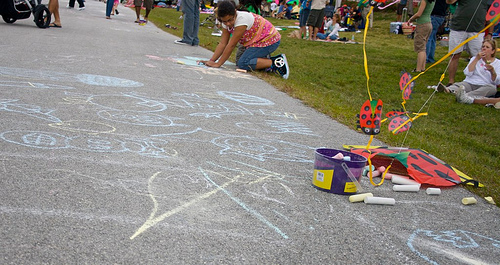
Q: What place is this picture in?
A: It is at the pavement.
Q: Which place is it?
A: It is a pavement.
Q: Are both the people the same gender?
A: Yes, all the people are female.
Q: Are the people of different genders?
A: No, all the people are female.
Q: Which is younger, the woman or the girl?
A: The girl is younger than the woman.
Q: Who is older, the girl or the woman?
A: The woman is older than the girl.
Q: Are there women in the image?
A: Yes, there is a woman.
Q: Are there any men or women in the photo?
A: Yes, there is a woman.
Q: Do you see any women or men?
A: Yes, there is a woman.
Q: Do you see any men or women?
A: Yes, there is a woman.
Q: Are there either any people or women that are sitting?
A: Yes, the woman is sitting.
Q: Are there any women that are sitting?
A: Yes, there is a woman that is sitting.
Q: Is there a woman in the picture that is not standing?
A: Yes, there is a woman that is sitting.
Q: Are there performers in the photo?
A: No, there are no performers.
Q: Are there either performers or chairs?
A: No, there are no performers or chairs.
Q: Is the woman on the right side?
A: Yes, the woman is on the right of the image.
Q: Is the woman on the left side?
A: No, the woman is on the right of the image.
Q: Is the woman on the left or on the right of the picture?
A: The woman is on the right of the image.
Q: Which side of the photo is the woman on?
A: The woman is on the right of the image.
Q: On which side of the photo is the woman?
A: The woman is on the right of the image.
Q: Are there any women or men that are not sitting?
A: No, there is a woman but she is sitting.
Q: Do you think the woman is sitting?
A: Yes, the woman is sitting.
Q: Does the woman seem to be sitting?
A: Yes, the woman is sitting.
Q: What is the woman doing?
A: The woman is sitting.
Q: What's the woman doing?
A: The woman is sitting.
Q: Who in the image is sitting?
A: The woman is sitting.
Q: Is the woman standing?
A: No, the woman is sitting.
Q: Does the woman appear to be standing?
A: No, the woman is sitting.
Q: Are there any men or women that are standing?
A: No, there is a woman but she is sitting.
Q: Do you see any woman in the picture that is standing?
A: No, there is a woman but she is sitting.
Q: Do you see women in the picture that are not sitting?
A: No, there is a woman but she is sitting.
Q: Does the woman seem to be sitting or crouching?
A: The woman is sitting.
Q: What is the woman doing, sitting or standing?
A: The woman is sitting.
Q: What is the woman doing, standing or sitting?
A: The woman is sitting.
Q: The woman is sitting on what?
A: The woman is sitting on the grass.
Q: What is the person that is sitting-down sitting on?
A: The woman is sitting on the grass.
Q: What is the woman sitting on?
A: The woman is sitting on the grass.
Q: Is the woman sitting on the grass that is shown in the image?
A: Yes, the woman is sitting on the grass.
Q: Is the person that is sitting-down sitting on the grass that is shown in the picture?
A: Yes, the woman is sitting on the grass.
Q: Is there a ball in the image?
A: No, there are no balls.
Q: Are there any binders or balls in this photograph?
A: No, there are no balls or binders.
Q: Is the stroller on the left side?
A: Yes, the stroller is on the left of the image.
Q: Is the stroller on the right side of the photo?
A: No, the stroller is on the left of the image.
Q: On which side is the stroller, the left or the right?
A: The stroller is on the left of the image.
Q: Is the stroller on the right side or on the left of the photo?
A: The stroller is on the left of the image.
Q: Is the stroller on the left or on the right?
A: The stroller is on the left of the image.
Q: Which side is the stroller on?
A: The stroller is on the left of the image.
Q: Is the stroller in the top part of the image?
A: Yes, the stroller is in the top of the image.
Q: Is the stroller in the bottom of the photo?
A: No, the stroller is in the top of the image.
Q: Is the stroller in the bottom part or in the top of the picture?
A: The stroller is in the top of the image.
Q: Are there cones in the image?
A: No, there are no cones.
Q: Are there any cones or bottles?
A: No, there are no cones or bottles.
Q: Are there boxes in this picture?
A: No, there are no boxes.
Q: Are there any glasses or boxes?
A: No, there are no boxes or glasses.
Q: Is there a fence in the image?
A: No, there are no fences.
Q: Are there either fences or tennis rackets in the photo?
A: No, there are no fences or tennis rackets.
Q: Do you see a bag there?
A: No, there are no bags.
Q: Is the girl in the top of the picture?
A: Yes, the girl is in the top of the image.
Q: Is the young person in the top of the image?
A: Yes, the girl is in the top of the image.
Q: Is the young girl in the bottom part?
A: No, the girl is in the top of the image.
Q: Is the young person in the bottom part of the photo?
A: No, the girl is in the top of the image.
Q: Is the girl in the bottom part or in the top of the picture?
A: The girl is in the top of the image.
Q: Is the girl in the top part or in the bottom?
A: The girl is in the top of the image.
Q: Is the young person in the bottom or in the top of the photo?
A: The girl is in the top of the image.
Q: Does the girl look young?
A: Yes, the girl is young.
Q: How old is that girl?
A: The girl is young.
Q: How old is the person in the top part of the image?
A: The girl is young.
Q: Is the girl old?
A: No, the girl is young.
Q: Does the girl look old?
A: No, the girl is young.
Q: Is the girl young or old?
A: The girl is young.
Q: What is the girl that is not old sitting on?
A: The girl is sitting on the grass.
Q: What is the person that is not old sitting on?
A: The girl is sitting on the grass.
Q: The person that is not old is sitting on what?
A: The girl is sitting on the grass.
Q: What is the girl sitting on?
A: The girl is sitting on the grass.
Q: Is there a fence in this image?
A: No, there are no fences.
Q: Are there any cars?
A: No, there are no cars.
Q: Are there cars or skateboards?
A: No, there are no cars or skateboards.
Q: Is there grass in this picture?
A: Yes, there is grass.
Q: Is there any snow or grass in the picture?
A: Yes, there is grass.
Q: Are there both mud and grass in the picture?
A: No, there is grass but no mud.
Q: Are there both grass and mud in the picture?
A: No, there is grass but no mud.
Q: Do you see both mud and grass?
A: No, there is grass but no mud.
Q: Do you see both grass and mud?
A: No, there is grass but no mud.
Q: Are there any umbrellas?
A: No, there are no umbrellas.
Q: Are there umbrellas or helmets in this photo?
A: No, there are no umbrellas or helmets.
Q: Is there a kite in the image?
A: Yes, there is a kite.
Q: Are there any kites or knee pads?
A: Yes, there is a kite.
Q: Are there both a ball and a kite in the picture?
A: No, there is a kite but no balls.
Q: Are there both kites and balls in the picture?
A: No, there is a kite but no balls.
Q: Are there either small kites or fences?
A: Yes, there is a small kite.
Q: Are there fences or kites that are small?
A: Yes, the kite is small.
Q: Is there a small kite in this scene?
A: Yes, there is a small kite.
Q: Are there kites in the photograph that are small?
A: Yes, there is a small kite.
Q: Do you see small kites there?
A: Yes, there is a small kite.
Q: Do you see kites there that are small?
A: Yes, there is a small kite.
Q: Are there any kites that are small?
A: Yes, there is a kite that is small.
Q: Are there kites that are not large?
A: Yes, there is a small kite.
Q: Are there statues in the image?
A: No, there are no statues.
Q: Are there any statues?
A: No, there are no statues.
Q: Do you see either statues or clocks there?
A: No, there are no statues or clocks.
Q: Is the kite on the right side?
A: Yes, the kite is on the right of the image.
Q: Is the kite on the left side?
A: No, the kite is on the right of the image.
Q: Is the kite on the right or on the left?
A: The kite is on the right of the image.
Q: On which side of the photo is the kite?
A: The kite is on the right of the image.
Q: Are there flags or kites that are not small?
A: No, there is a kite but it is small.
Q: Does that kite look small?
A: Yes, the kite is small.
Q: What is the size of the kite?
A: The kite is small.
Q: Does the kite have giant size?
A: No, the kite is small.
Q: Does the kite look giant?
A: No, the kite is small.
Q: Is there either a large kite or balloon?
A: No, there is a kite but it is small.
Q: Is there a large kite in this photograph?
A: No, there is a kite but it is small.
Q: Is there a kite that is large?
A: No, there is a kite but it is small.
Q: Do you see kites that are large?
A: No, there is a kite but it is small.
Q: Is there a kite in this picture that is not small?
A: No, there is a kite but it is small.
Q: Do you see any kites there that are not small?
A: No, there is a kite but it is small.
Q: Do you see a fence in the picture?
A: No, there are no fences.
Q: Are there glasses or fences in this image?
A: No, there are no fences or glasses.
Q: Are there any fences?
A: No, there are no fences.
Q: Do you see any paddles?
A: No, there are no paddles.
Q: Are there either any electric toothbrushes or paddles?
A: No, there are no paddles or electric toothbrushes.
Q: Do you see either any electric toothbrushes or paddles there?
A: No, there are no paddles or electric toothbrushes.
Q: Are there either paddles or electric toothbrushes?
A: No, there are no paddles or electric toothbrushes.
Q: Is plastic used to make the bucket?
A: Yes, the bucket is made of plastic.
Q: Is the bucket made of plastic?
A: Yes, the bucket is made of plastic.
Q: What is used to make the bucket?
A: The bucket is made of plastic.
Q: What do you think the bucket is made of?
A: The bucket is made of plastic.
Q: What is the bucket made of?
A: The bucket is made of plastic.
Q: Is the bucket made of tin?
A: No, the bucket is made of plastic.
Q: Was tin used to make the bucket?
A: No, the bucket is made of plastic.